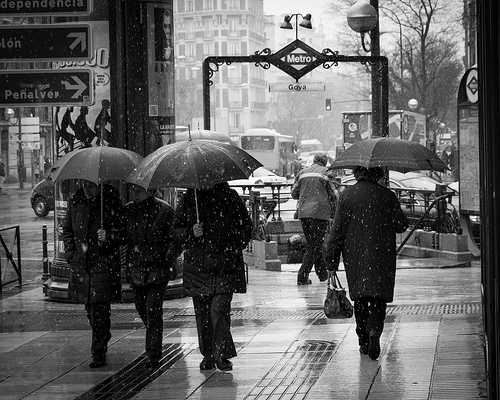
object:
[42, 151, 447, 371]
people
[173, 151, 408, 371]
people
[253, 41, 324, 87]
sign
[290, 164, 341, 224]
jacket